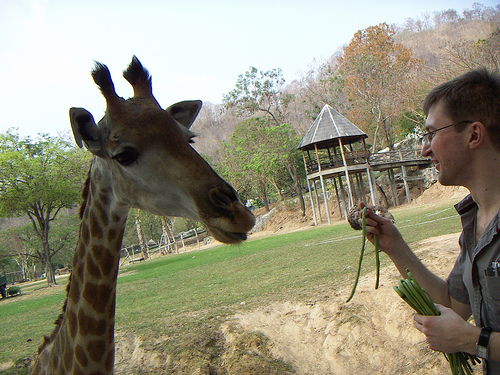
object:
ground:
[348, 160, 438, 223]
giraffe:
[28, 42, 285, 371]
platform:
[301, 101, 398, 230]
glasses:
[417, 120, 480, 142]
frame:
[426, 118, 473, 133]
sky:
[7, 0, 482, 149]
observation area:
[303, 86, 384, 252]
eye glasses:
[420, 116, 498, 147]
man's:
[360, 65, 498, 372]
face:
[415, 92, 490, 187]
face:
[58, 97, 254, 246]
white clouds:
[7, 5, 160, 101]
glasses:
[411, 114, 485, 154]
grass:
[2, 233, 465, 374]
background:
[3, 5, 496, 280]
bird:
[326, 171, 413, 252]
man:
[360, 65, 497, 371]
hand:
[403, 303, 475, 356]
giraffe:
[44, 29, 277, 369]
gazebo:
[300, 104, 430, 225]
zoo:
[0, 0, 497, 372]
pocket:
[483, 274, 498, 314]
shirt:
[444, 193, 497, 371]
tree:
[3, 125, 112, 287]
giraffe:
[0, 57, 258, 367]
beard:
[204, 225, 253, 248]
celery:
[348, 205, 380, 303]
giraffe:
[27, 53, 257, 372]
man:
[320, 70, 488, 371]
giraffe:
[19, 52, 281, 327]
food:
[393, 271, 476, 371]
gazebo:
[300, 102, 378, 224]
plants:
[375, 274, 438, 335]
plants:
[335, 194, 390, 298]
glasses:
[409, 120, 483, 154]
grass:
[0, 220, 496, 373]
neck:
[29, 54, 269, 370]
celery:
[388, 266, 481, 374]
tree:
[4, 137, 90, 214]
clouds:
[4, 2, 224, 113]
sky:
[1, 1, 497, 195]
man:
[345, 57, 475, 367]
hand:
[348, 188, 408, 255]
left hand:
[415, 300, 472, 357]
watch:
[466, 318, 484, 360]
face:
[422, 105, 453, 186]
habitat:
[3, 125, 484, 371]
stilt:
[317, 175, 331, 228]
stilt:
[300, 173, 319, 224]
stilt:
[310, 179, 324, 222]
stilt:
[346, 171, 359, 215]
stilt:
[360, 163, 379, 212]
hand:
[356, 204, 397, 257]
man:
[341, 57, 484, 352]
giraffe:
[7, 47, 267, 368]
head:
[56, 46, 264, 254]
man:
[343, 56, 483, 370]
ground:
[4, 160, 474, 342]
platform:
[294, 96, 384, 236]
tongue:
[218, 228, 248, 242]